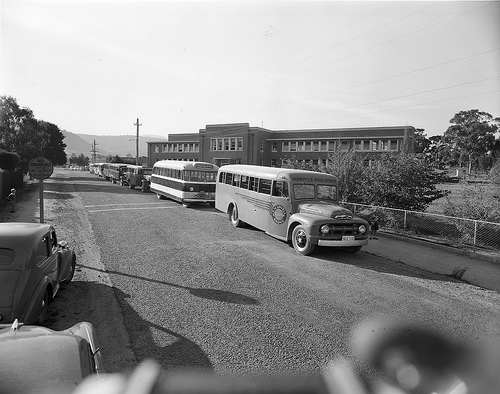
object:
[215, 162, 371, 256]
bus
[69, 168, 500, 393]
street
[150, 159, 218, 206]
bus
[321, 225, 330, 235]
headlight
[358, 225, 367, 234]
headlight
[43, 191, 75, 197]
shadow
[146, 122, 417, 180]
building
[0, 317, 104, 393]
car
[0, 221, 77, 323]
car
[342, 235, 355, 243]
plate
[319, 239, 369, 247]
bumper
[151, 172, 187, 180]
rail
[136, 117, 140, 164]
pole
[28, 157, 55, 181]
sign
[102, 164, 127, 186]
bus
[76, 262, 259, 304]
shadow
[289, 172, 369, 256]
front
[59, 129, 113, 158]
mountains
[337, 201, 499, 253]
fence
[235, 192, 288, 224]
logo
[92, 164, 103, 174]
bus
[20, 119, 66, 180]
tree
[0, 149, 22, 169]
tree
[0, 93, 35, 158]
tree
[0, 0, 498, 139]
sky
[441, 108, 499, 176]
tree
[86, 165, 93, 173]
bus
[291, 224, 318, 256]
wheel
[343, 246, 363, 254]
wheel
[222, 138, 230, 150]
windows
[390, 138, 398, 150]
windows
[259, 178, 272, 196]
windows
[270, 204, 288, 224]
circle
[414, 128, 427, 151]
tree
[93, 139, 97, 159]
pole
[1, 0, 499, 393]
photo